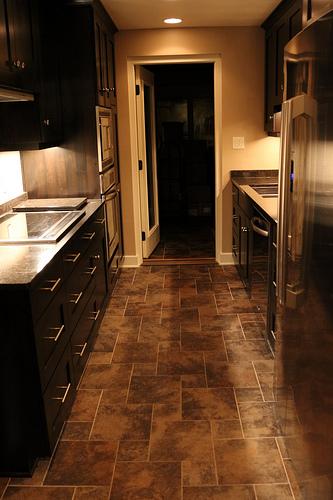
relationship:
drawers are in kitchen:
[13, 202, 121, 444] [0, 3, 332, 497]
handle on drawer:
[39, 267, 65, 299] [27, 258, 69, 312]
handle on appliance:
[248, 216, 269, 239] [247, 203, 275, 327]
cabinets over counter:
[0, 0, 77, 155] [2, 183, 115, 290]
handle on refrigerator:
[277, 95, 306, 309] [274, 10, 332, 489]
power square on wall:
[228, 132, 250, 157] [115, 27, 283, 283]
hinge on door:
[130, 148, 147, 182] [130, 63, 172, 258]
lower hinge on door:
[139, 223, 149, 248] [130, 63, 172, 258]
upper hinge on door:
[130, 76, 142, 107] [130, 63, 172, 258]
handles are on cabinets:
[13, 59, 60, 138] [2, 3, 75, 153]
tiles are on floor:
[134, 269, 220, 323] [72, 261, 290, 497]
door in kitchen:
[130, 63, 172, 258] [0, 3, 332, 497]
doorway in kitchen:
[119, 54, 232, 268] [0, 3, 332, 497]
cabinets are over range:
[2, 3, 75, 153] [2, 203, 88, 248]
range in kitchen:
[2, 203, 88, 248] [0, 3, 332, 497]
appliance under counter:
[247, 203, 275, 327] [247, 191, 298, 236]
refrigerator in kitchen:
[274, 10, 332, 489] [0, 3, 332, 497]